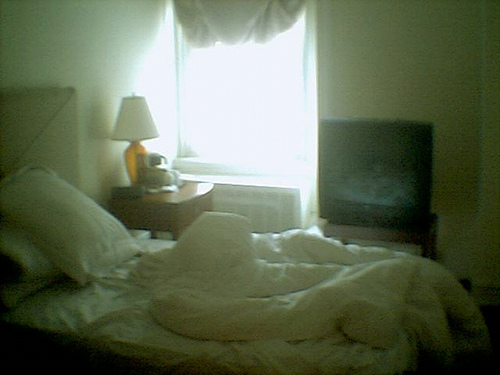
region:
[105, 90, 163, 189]
lamp with white shade on table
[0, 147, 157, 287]
white pillow lying on the bed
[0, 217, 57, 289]
white pillow lying on the bed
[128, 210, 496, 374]
white blankets lying on the bed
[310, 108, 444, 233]
old style black tv on a stand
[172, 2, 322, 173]
window with light streaming through it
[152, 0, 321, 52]
white curtain above a window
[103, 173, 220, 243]
brown wooden night stand with things on it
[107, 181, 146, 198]
black plastic alarm clock on night stand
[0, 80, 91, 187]
white head board above a bed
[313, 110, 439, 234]
small black tube television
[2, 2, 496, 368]
messy room with bed, nightstand and television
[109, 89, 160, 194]
yellow lamp with white lampshade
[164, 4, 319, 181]
window with light coming through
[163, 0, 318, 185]
window with curtains pulled up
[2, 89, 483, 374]
bed with white linens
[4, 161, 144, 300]
two white pillows on bed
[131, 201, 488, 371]
crumpled messy white comforter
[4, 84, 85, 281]
light colored headboard on wall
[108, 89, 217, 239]
brown wood nightstand with lamp on top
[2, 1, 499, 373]
a blurry, largely white, sunlit bedroom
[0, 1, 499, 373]
@ least a couple of white plump comforter type things, including where they dont ordinarily belong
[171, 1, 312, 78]
a comforter, or duvet, or something curled up & secured above a bright window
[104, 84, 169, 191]
a white semi-conical lampshaded amber colour lamp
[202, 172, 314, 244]
a radiator or a/c, i think the former, but beneath a window?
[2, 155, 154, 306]
a vertical pillow atop a horizontal pillow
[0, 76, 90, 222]
a headboard, looking from this angle like a brown envelope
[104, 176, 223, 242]
a lightly curved wooden nightstand with thin wooden legs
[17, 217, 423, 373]
at least one somewhat crumpled sheet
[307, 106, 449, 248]
why the h-e-double-toothpicks would a television be the focus of an adult bedroom??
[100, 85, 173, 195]
lamp on night stand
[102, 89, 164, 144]
white lamp shade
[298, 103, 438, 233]
television on table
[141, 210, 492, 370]
white comforter on bed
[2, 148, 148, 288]
white pillow at top of bed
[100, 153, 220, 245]
wooden night stand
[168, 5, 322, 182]
window in bedroom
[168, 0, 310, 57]
short white drape at top of window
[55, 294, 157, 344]
wrinkle on white bed sheets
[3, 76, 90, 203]
tan head board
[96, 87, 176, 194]
lamp on nightstand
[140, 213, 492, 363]
white crumpled comforter on bed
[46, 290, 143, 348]
wrinkled bed sheets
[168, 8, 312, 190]
bedroom window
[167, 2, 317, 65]
draped over bedroom windows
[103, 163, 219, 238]
wooden night table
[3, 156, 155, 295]
white pillows at head of bed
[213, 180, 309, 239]
vent underneath window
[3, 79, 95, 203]
tan headboard